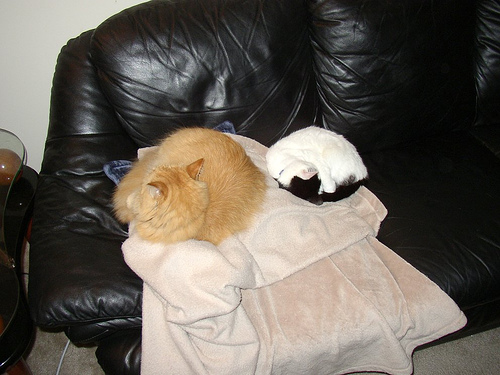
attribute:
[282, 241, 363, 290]
blanket — tan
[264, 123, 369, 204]
cat — white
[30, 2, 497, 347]
couch — shiney, black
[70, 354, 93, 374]
carpet — grey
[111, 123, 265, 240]
cat — orange